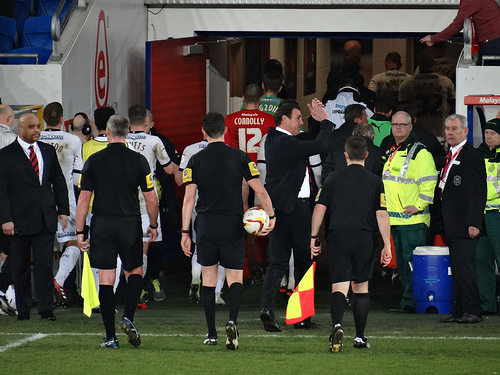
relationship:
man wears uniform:
[75, 113, 157, 347] [78, 141, 154, 271]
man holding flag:
[308, 134, 393, 354] [287, 237, 322, 324]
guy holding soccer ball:
[179, 111, 275, 350] [240, 202, 302, 247]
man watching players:
[432, 105, 489, 326] [55, 95, 439, 367]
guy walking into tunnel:
[179, 111, 275, 350] [65, 3, 148, 110]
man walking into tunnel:
[308, 134, 393, 354] [65, 3, 148, 110]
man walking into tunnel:
[75, 114, 159, 349] [65, 3, 148, 110]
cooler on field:
[407, 245, 453, 315] [5, 331, 497, 372]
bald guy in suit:
[0, 112, 72, 320] [0, 138, 71, 315]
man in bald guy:
[430, 114, 488, 325] [0, 112, 72, 320]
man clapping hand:
[257, 95, 338, 333] [307, 91, 323, 118]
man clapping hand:
[257, 95, 338, 333] [311, 99, 328, 129]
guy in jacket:
[380, 110, 438, 314] [380, 141, 437, 230]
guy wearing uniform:
[179, 111, 275, 350] [183, 137, 264, 275]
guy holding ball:
[179, 111, 275, 350] [238, 205, 268, 237]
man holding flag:
[306, 123, 415, 373] [281, 258, 315, 325]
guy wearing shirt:
[380, 110, 438, 314] [375, 142, 439, 227]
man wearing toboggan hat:
[475, 118, 499, 133] [475, 109, 498, 136]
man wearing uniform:
[75, 114, 159, 349] [66, 139, 155, 352]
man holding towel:
[75, 114, 159, 349] [74, 242, 107, 322]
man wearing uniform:
[75, 114, 159, 349] [66, 138, 166, 350]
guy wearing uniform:
[179, 111, 275, 350] [175, 137, 267, 352]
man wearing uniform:
[308, 134, 393, 354] [305, 153, 393, 355]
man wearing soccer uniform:
[163, 67, 278, 336] [184, 147, 244, 271]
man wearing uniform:
[308, 134, 393, 354] [314, 159, 390, 289]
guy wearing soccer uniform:
[179, 111, 275, 350] [181, 140, 261, 270]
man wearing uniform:
[308, 134, 393, 354] [315, 164, 389, 283]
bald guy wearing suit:
[0, 112, 72, 320] [3, 132, 83, 307]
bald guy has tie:
[0, 112, 72, 320] [10, 134, 51, 177]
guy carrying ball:
[179, 111, 275, 350] [242, 205, 269, 235]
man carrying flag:
[75, 114, 159, 349] [285, 269, 338, 330]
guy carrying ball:
[172, 109, 274, 353] [242, 206, 271, 236]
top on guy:
[377, 156, 444, 213] [361, 92, 453, 218]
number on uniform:
[234, 121, 268, 159] [223, 103, 280, 174]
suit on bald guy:
[431, 138, 491, 315] [2, 111, 72, 323]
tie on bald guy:
[28, 145, 38, 175] [0, 112, 72, 320]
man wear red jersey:
[220, 77, 277, 165] [220, 107, 278, 165]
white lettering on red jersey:
[230, 110, 270, 154] [220, 107, 278, 165]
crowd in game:
[6, 53, 492, 360] [4, 74, 498, 346]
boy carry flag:
[302, 123, 394, 361] [280, 256, 326, 330]